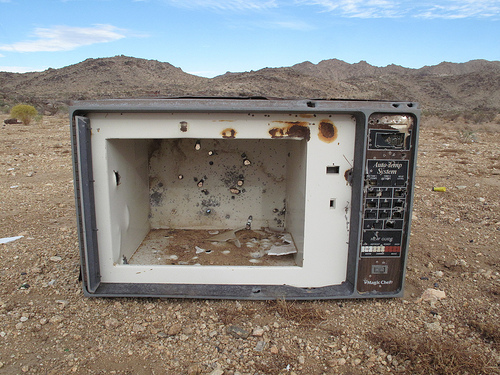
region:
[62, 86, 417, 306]
white rusted out microwave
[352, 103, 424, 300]
brown, black, and white microwave dial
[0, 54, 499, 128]
rocky brown hills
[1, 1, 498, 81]
bright blue clear sky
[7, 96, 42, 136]
small yellowish green bush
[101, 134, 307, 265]
inside of a rusted out microwave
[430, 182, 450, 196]
small yellow object in the dirt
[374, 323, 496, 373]
dead brown vegetation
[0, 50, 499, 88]
horizon line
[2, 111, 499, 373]
rocky brown dirt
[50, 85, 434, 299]
a microwave in the desert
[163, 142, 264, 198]
bullet holes in a microwave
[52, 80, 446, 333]
microwave with a missing door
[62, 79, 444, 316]
microwave needing some repairs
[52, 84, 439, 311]
microwave needing at least a long extension cord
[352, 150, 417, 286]
control panel of the microwave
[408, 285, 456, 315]
small rock on the ground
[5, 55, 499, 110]
hilly area in the distance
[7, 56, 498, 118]
hilly area in the background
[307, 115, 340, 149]
rusty area surrounding a hole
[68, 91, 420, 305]
a piece of junk is in the desert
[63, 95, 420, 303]
the piece of junk is dumped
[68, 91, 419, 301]
the door is off the microwave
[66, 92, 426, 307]
the microwave's door is missing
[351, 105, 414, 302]
the keypad has holes in it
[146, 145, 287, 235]
holes are through the back wall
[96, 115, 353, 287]
the interior of the microwave is white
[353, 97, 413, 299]
the keypad is brown and black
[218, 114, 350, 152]
the oven is rusted in places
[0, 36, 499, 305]
hills are behind the oven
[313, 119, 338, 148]
Brown spot on the microwave.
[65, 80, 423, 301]
The microwave is old.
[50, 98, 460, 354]
The door is missing.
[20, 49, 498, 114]
The hills are dirt.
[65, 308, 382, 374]
The terrain is rocky.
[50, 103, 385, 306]
The inside is white.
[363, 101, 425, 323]
The buttons are black and brown.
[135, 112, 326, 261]
The holes are in the back of the microwave.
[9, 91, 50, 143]
The bush is dead.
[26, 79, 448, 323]
microwave on the dirt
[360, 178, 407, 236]
buttons on the microwave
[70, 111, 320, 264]
microwave with no door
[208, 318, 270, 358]
rocks under the microwave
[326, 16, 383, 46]
sky above the mountains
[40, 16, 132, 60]
clouds in the sky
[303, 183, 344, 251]
white part of microwave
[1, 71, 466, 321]
broken down microwave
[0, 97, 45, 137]
bush behind the microwave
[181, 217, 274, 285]
dirt in the bottom of the microwave